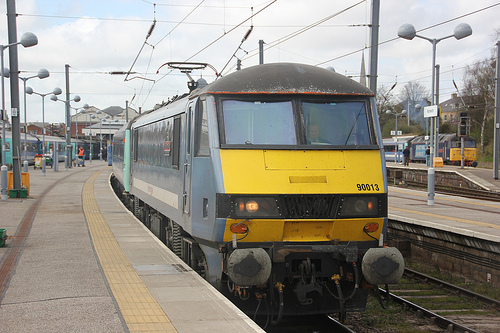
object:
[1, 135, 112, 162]
train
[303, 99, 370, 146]
window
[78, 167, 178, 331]
yellow brick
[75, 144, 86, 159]
sweater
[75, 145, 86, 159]
vest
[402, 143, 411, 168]
person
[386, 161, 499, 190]
platform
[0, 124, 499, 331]
station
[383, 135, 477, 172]
train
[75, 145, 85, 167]
person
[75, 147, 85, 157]
orange vest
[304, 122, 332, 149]
driver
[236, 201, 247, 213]
light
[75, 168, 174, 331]
line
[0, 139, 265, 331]
sidewalk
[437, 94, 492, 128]
brick building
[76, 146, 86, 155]
orange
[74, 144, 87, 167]
man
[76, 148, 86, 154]
jacket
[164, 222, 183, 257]
wheel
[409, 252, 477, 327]
railroad tracks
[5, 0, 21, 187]
pole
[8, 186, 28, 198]
base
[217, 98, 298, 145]
window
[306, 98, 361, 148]
conductor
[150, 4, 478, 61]
wires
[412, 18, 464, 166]
street lights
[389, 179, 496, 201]
track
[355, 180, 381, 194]
number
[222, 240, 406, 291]
brakes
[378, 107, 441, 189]
man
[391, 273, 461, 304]
grass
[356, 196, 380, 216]
headlight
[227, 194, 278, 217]
headlight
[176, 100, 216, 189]
window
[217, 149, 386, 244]
paint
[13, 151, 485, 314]
platform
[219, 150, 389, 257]
front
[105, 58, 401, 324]
train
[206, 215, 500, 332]
track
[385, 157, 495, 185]
sidewalk